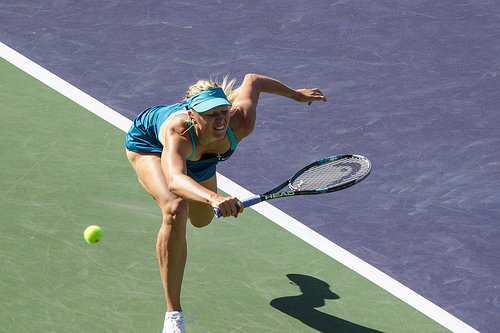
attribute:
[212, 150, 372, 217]
racket — tennis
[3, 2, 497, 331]
tennis court — blue, green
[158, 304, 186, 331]
sneaker — white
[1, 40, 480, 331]
line — white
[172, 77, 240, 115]
visor — blue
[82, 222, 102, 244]
tennis ball — round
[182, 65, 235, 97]
hair — blonde